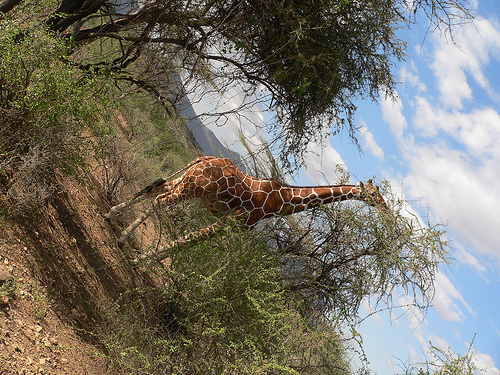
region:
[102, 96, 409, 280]
it is a giraffe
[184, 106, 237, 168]
it is a mountain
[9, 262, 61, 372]
it is a ground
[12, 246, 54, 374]
small stones visible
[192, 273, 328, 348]
it is green color plants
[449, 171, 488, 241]
it is white color cloud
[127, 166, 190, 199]
it is giraffe tail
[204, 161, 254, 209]
giraffe is brown with white color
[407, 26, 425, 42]
this is the sky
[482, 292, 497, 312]
the sky is blue in color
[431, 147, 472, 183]
the clouds are white in color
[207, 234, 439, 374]
these are some plants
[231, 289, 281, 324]
the leaves are green in color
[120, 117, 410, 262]
this is a giraffe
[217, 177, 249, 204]
the fur is brown in color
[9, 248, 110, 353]
this is the ground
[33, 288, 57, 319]
the sand is brown in color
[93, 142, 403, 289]
A giraffe eating leaves from a tree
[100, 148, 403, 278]
A giraffe eating leaves from a tree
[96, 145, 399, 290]
A giraffe eating leaves from a tree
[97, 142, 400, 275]
A giraffe eating leaves from a tree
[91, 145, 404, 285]
A giraffe eating leaves from a tree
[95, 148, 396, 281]
A giraffe eating leaves from a tree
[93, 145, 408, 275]
A giraffe eating leaves from a tree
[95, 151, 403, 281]
A giraffe eating leaves from a tree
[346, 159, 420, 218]
head of the giraffe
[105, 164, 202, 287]
legs of the giraffe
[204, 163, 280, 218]
brown and white giraffe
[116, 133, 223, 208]
tail of the giraffe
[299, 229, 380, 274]
branches on the tree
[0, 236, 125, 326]
shadows on the ground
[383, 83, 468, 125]
blue sky behind clouds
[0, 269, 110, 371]
rocks on the ground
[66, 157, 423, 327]
one giraffe in the photo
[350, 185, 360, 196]
brown spot on giraffe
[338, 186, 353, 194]
brown spot on giraffe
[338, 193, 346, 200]
brown spot on giraffe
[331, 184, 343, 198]
brown spot on giraffe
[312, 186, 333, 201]
brown spot on giraffe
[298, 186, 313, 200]
brown spot on giraffe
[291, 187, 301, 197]
brown spot on giraffe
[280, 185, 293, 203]
brown spot on giraffe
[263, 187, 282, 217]
brown spot on giraffe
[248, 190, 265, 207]
brown spot on giraffe